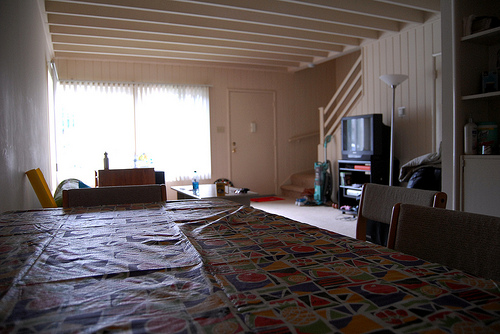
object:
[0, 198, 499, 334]
tablecloth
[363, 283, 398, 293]
pattern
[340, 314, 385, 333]
pattern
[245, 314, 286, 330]
pattern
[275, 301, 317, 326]
pattern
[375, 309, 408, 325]
pattern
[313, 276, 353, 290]
pattern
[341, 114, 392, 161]
tv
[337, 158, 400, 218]
stand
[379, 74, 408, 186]
lamp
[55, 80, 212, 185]
window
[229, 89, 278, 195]
door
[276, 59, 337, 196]
wall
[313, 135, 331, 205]
vaccum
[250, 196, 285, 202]
floormat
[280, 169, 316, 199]
stairs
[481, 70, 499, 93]
item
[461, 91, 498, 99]
shelf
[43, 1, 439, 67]
beam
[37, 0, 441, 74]
ceiling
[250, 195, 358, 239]
floor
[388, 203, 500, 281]
chair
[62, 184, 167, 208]
chair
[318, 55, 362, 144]
bannister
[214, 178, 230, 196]
item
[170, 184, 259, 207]
coffee table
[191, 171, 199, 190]
bottle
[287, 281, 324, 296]
rectangle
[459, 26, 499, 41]
shelf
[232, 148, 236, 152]
knob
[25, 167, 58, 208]
yellow piece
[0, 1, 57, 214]
wall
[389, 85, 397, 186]
pole